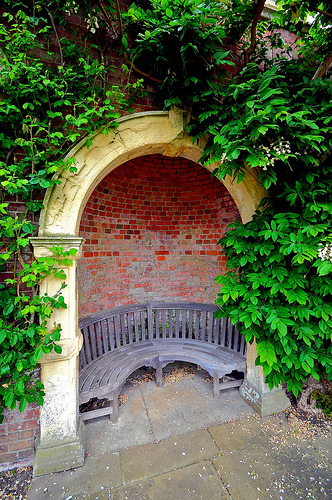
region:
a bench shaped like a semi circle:
[30, 291, 288, 421]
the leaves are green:
[200, 151, 329, 439]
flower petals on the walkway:
[52, 377, 329, 496]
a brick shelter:
[68, 142, 255, 334]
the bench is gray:
[71, 290, 253, 436]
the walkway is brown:
[44, 374, 310, 498]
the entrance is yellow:
[26, 104, 305, 438]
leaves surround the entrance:
[0, 1, 326, 447]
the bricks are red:
[84, 175, 238, 343]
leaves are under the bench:
[92, 348, 237, 430]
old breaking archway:
[43, 63, 301, 471]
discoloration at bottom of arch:
[1, 349, 93, 495]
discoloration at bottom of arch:
[222, 358, 292, 428]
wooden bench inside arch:
[58, 288, 253, 424]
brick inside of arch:
[69, 162, 226, 312]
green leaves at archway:
[0, 65, 66, 409]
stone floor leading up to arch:
[71, 416, 296, 498]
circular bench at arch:
[64, 276, 235, 417]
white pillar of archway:
[8, 183, 93, 395]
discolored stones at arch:
[101, 198, 207, 308]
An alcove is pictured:
[12, 102, 305, 481]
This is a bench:
[77, 311, 247, 419]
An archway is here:
[36, 113, 269, 294]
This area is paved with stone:
[100, 428, 298, 498]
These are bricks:
[106, 184, 217, 287]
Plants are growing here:
[231, 121, 329, 360]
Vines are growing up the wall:
[6, 117, 56, 416]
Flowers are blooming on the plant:
[250, 136, 293, 173]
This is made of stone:
[26, 235, 94, 473]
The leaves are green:
[211, 58, 316, 133]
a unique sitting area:
[31, 219, 300, 477]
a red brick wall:
[78, 146, 271, 315]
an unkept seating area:
[13, 346, 328, 495]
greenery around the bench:
[10, 186, 330, 415]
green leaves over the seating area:
[9, 4, 318, 186]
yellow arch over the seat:
[28, 94, 317, 334]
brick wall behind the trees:
[48, 5, 315, 93]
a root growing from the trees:
[272, 350, 330, 426]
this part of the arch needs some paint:
[9, 377, 127, 489]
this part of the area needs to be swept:
[118, 362, 331, 495]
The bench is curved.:
[44, 276, 265, 409]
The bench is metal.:
[42, 288, 293, 398]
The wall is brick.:
[70, 143, 263, 359]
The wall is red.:
[66, 165, 246, 337]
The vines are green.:
[194, 63, 321, 192]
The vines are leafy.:
[165, 44, 324, 181]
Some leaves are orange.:
[237, 19, 302, 63]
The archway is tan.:
[17, 114, 292, 446]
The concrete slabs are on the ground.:
[121, 408, 260, 498]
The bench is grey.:
[71, 286, 276, 453]